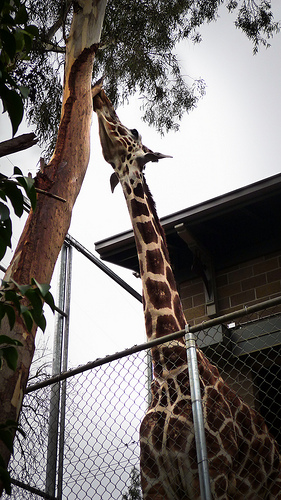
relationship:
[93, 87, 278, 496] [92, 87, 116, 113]
giraffe has giraffe's mouth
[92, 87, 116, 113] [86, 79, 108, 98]
giraffe's mouth touching branch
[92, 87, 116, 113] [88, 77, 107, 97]
giraffe's mouth on branch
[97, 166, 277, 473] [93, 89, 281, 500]
facility for giraffe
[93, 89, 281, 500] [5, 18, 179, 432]
giraffe standing under tree branches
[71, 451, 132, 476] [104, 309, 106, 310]
power lines in sky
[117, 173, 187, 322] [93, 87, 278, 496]
neck of giraffe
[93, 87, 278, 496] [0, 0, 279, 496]
giraffe reaches for th tree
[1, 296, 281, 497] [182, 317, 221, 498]
fence has post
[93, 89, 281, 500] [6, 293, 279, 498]
giraffe in fence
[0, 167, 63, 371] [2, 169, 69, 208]
leaves on branches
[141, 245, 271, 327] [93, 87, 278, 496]
building behind giraffe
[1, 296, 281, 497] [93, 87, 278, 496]
fence surrounding giraffe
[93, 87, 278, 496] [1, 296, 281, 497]
giraffe behind fence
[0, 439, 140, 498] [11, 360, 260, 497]
powerlines behind fence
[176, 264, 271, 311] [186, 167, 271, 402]
bricks on building